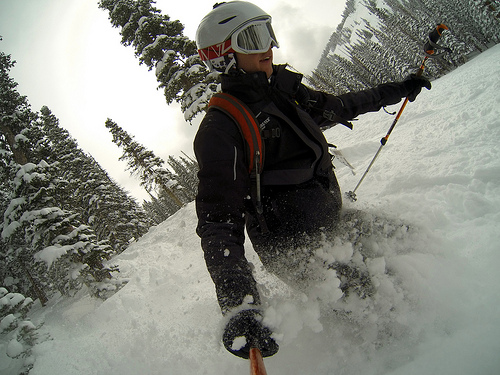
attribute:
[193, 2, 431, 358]
person — kicking, skiing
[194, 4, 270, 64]
helmet — white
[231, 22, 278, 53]
goggles — white, shiny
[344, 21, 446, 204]
ski pole — black, orange, held, downhill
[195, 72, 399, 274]
jacket — black, winter, brown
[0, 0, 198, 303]
trees — pine, tall, covered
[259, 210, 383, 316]
snow — airborne, spraying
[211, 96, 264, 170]
strap — red, black, orange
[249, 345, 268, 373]
ski pole — held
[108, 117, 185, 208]
tree — covered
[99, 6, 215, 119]
tree — covered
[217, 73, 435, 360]
gloves — winter, black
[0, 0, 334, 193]
sky — gray, grey, cloudy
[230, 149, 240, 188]
stripes — white